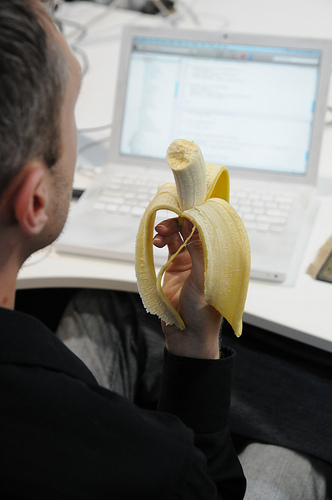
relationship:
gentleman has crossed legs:
[0, 3, 330, 499] [63, 292, 319, 496]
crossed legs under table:
[63, 292, 319, 496] [25, 248, 331, 339]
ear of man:
[13, 167, 53, 248] [0, 42, 268, 495]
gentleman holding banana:
[0, 3, 330, 499] [123, 120, 262, 335]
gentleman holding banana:
[0, 3, 330, 499] [118, 130, 286, 378]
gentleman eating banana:
[0, 3, 330, 499] [128, 133, 251, 340]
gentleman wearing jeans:
[0, 3, 330, 499] [52, 287, 331, 497]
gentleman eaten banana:
[0, 3, 246, 497] [107, 144, 251, 353]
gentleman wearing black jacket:
[0, 3, 330, 499] [0, 310, 249, 499]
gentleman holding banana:
[0, 3, 330, 499] [128, 133, 251, 340]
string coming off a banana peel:
[154, 223, 200, 291] [180, 197, 250, 337]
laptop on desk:
[54, 24, 329, 285] [87, 146, 330, 347]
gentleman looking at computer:
[0, 3, 330, 499] [60, 14, 326, 283]